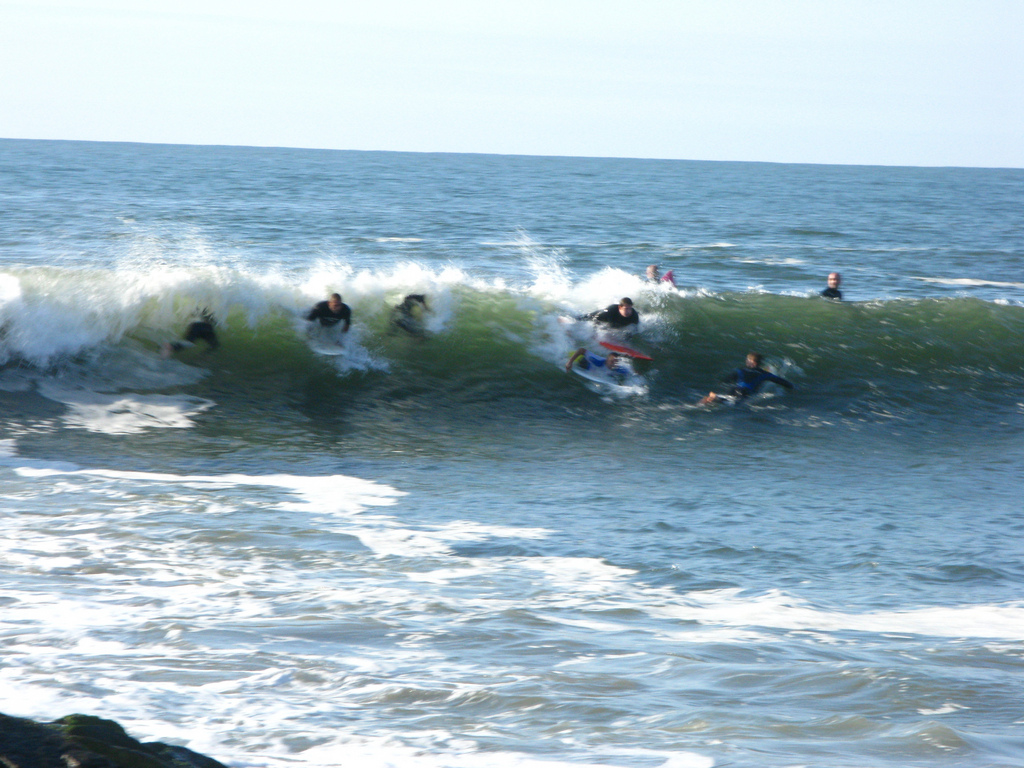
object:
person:
[565, 347, 638, 386]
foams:
[309, 240, 437, 307]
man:
[302, 290, 355, 346]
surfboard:
[306, 340, 343, 357]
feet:
[705, 390, 717, 403]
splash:
[132, 234, 475, 312]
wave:
[0, 232, 1023, 398]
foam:
[36, 364, 222, 440]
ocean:
[0, 134, 1024, 767]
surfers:
[158, 294, 233, 368]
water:
[0, 130, 1023, 300]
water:
[3, 308, 1023, 763]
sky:
[0, 0, 1024, 171]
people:
[576, 295, 645, 334]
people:
[565, 345, 642, 385]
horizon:
[0, 134, 1022, 178]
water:
[0, 132, 1024, 767]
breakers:
[255, 453, 413, 529]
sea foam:
[0, 262, 137, 362]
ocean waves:
[2, 222, 744, 370]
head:
[617, 296, 635, 318]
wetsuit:
[713, 366, 795, 407]